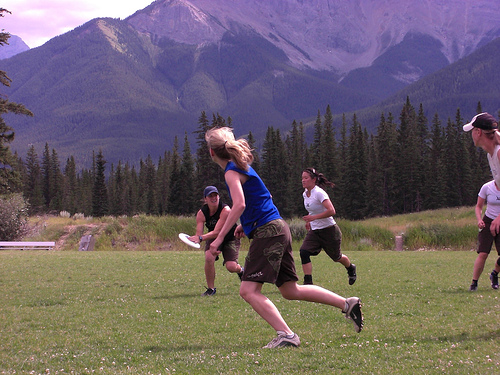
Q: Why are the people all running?
A: Playing a game.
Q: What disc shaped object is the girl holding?
A: Frisbee.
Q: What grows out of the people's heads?
A: Hair.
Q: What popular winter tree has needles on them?
A: Evergreens.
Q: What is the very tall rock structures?
A: Mountains.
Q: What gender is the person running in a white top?
A: Female.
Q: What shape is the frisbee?
A: Circle.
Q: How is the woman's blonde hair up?
A: Ponytail.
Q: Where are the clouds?
A: The sky.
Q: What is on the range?
A: Snow.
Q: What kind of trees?
A: Pine.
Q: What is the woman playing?
A: Frisbee.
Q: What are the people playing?
A: Frisbee.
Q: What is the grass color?
A: Green.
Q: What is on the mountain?
A: Trees.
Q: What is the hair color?
A: Blonde.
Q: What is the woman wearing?
A: Cleats.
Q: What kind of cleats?
A: Nike.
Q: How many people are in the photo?
A: Five.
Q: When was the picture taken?
A: Daytime.